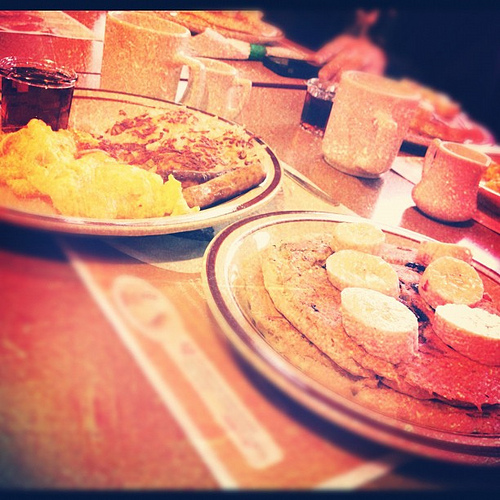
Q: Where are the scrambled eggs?
A: Plate.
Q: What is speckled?
A: Mug.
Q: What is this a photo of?
A: Golden brown hashbrowns on plate.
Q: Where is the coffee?
A: In the mugs.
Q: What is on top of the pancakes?
A: Bananas.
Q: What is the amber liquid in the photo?
A: Maple syrup.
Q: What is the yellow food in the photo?
A: Eggs.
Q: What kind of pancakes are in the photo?
A: Blueberry.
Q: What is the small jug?
A: Creamer for coffee.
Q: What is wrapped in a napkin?
A: Silverware.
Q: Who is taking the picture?
A: A photographer.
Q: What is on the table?
A: Plates of food.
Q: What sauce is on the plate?
A: Syrup.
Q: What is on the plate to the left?
A: Eggs.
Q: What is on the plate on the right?
A: Pancakes.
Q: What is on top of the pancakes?
A: Bananas.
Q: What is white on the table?
A: Cups.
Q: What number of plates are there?
A: There are 5 plates.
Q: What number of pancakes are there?
A: 2.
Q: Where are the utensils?
A: Wrapped in a napkin.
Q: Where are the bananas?
A: On the pancakes.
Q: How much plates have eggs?
A: One.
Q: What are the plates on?
A: A table.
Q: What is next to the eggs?
A: Hashbrowns and sausage.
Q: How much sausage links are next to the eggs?
A: One.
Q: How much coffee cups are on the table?
A: Two.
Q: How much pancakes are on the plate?
A: Two.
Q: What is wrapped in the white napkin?
A: Utensils.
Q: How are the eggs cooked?
A: Scrambled.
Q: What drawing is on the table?
A: A spoon.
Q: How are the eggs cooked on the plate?
A: Scrambled.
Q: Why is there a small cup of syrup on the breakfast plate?
A: For the pancakes.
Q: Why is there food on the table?
A: The people are having a meal.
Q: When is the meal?
A: Breakfast time.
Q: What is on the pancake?
A: Pieces of banana.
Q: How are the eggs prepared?
A: Scrambled.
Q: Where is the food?
A: On the table.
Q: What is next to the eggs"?
A: Sausage,hash browns and a drink.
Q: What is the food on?
A: Plates.